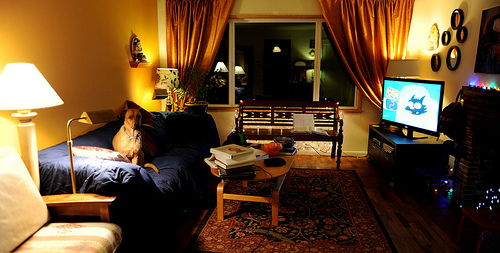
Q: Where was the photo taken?
A: In a living room.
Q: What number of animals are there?
A: One.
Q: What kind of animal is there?
A: A dog.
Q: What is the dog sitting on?
A: A couch.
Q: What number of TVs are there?
A: One.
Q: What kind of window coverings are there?
A: Curtains.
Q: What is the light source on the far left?
A: A lamp.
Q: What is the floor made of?
A: Wood.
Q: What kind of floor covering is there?
A: A rug.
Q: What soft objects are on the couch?
A: Pillows.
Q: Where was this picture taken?
A: In a home.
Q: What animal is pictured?
A: Dog.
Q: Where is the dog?
A: On the sofa.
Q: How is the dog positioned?
A: Sitting.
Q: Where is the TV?
A: On the table.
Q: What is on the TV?
A: A cartoon.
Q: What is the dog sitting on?
A: A couch.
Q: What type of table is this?
A: Wooden coffee table.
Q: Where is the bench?
A: The living room.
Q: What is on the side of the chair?
A: A lamp.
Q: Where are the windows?
A: In the living room.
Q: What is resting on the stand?
A: A TV.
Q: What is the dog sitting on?
A: The couch.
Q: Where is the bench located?
A: In the living room.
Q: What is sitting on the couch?
A: Dog.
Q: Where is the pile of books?
A: On the table.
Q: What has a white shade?
A: Lamp.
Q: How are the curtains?
A: Pulled back.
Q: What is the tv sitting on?
A: Stand.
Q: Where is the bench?
A: By the window.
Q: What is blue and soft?
A: Slipcover.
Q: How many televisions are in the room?
A: One.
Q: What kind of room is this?
A: Living room.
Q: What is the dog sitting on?
A: Sofa.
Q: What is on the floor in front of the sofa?
A: Rug.